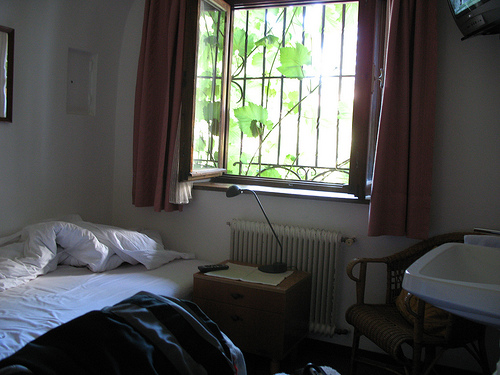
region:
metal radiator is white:
[229, 221, 364, 337]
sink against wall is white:
[401, 233, 497, 334]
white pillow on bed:
[61, 216, 193, 267]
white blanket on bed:
[0, 221, 128, 289]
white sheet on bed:
[4, 252, 219, 368]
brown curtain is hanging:
[130, 4, 223, 214]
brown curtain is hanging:
[366, 3, 434, 240]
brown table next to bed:
[195, 262, 309, 370]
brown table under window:
[194, 259, 311, 368]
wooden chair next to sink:
[345, 227, 485, 372]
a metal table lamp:
[225, 183, 287, 275]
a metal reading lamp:
[225, 185, 290, 273]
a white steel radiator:
[225, 215, 352, 340]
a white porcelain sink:
[401, 240, 496, 323]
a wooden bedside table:
[192, 258, 310, 374]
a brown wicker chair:
[344, 228, 493, 374]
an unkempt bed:
[0, 212, 220, 357]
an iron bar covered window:
[187, 0, 387, 198]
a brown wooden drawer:
[192, 272, 285, 318]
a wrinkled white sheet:
[0, 211, 216, 361]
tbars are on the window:
[160, 10, 426, 201]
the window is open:
[160, 9, 480, 202]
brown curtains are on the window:
[128, 0, 263, 187]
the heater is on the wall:
[215, 214, 391, 367]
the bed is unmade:
[34, 236, 170, 327]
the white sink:
[393, 233, 492, 331]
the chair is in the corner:
[338, 241, 450, 363]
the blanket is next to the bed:
[37, 282, 160, 368]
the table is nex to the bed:
[200, 240, 421, 348]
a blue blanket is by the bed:
[82, 305, 215, 355]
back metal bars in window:
[227, 8, 366, 194]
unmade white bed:
[2, 194, 200, 343]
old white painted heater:
[229, 205, 355, 334]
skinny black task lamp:
[221, 176, 306, 281]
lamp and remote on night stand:
[195, 185, 320, 322]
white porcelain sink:
[416, 220, 497, 315]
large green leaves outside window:
[235, 13, 340, 193]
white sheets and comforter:
[8, 204, 220, 341]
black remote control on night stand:
[189, 250, 237, 284]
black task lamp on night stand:
[222, 175, 293, 291]